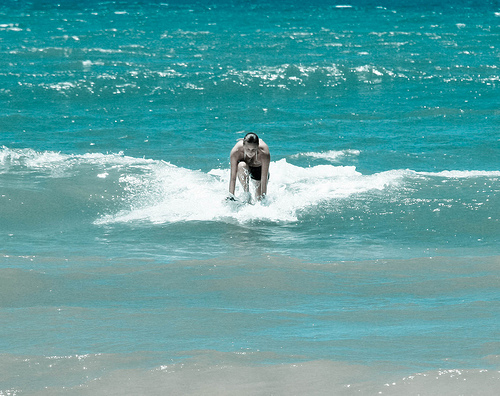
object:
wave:
[0, 152, 500, 230]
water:
[25, 53, 461, 280]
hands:
[224, 187, 269, 205]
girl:
[222, 128, 275, 204]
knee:
[235, 159, 248, 176]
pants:
[242, 167, 274, 186]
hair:
[239, 130, 261, 151]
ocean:
[182, 195, 461, 362]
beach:
[1, 342, 499, 395]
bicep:
[258, 154, 272, 177]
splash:
[149, 161, 206, 219]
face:
[241, 132, 262, 159]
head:
[240, 129, 262, 159]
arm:
[225, 145, 241, 203]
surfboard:
[221, 199, 274, 211]